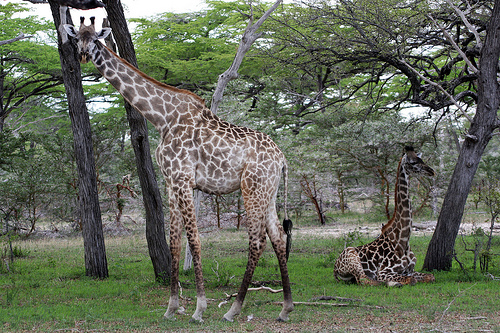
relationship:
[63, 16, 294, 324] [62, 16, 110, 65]
giraffe has a head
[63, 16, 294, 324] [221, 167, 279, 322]
giraffe has a leg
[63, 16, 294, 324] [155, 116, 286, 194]
giraffe has a body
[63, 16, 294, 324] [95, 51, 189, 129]
giraffe has a neck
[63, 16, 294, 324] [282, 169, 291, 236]
giraffe has a tail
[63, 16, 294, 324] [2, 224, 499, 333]
giraffe on ground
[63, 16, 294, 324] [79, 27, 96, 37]
giraffe has hair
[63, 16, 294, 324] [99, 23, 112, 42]
giraffe has an ear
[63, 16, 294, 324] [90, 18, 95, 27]
giraffe has a horn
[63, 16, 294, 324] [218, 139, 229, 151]
giraffe has spots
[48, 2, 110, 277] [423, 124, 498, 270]
tree has a trunk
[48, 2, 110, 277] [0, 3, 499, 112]
tree has leaves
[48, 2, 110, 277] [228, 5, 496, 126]
tree has branches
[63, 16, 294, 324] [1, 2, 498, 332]
giraffe in wild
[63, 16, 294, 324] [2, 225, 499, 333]
giraffe on grass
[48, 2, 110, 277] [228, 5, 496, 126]
tree has a branches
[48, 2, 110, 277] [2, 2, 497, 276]
tree are in distance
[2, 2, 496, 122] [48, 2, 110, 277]
sky above tree